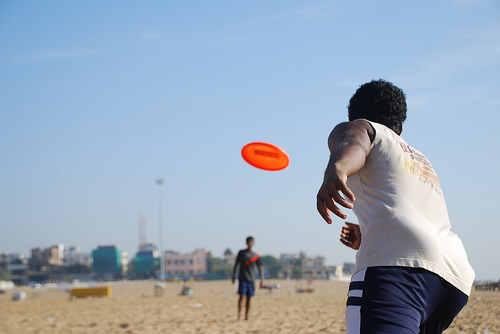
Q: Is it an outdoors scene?
A: Yes, it is outdoors.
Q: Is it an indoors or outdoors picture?
A: It is outdoors.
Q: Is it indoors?
A: No, it is outdoors.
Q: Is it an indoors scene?
A: No, it is outdoors.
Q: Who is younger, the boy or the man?
A: The boy is younger than the man.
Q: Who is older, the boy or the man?
A: The man is older than the boy.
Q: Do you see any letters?
A: Yes, there are letters.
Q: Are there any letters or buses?
A: Yes, there are letters.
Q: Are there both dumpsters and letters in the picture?
A: No, there are letters but no dumpsters.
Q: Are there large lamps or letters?
A: Yes, there are large letters.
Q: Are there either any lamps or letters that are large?
A: Yes, the letters are large.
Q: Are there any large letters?
A: Yes, there are large letters.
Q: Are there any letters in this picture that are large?
A: Yes, there are letters that are large.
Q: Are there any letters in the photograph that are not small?
A: Yes, there are large letters.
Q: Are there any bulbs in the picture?
A: No, there are no bulbs.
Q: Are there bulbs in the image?
A: No, there are no bulbs.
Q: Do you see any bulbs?
A: No, there are no bulbs.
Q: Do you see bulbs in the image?
A: No, there are no bulbs.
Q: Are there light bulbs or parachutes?
A: No, there are no light bulbs or parachutes.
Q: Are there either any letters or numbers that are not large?
A: No, there are letters but they are large.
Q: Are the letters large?
A: Yes, the letters are large.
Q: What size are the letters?
A: The letters are large.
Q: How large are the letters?
A: The letters are large.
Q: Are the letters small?
A: No, the letters are large.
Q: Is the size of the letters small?
A: No, the letters are large.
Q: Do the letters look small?
A: No, the letters are large.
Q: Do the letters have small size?
A: No, the letters are large.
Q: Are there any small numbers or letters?
A: No, there are letters but they are large.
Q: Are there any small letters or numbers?
A: No, there are letters but they are large.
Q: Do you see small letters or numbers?
A: No, there are letters but they are large.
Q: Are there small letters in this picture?
A: No, there are letters but they are large.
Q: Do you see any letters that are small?
A: No, there are letters but they are large.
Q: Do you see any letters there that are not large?
A: No, there are letters but they are large.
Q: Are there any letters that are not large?
A: No, there are letters but they are large.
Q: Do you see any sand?
A: Yes, there is sand.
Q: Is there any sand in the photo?
A: Yes, there is sand.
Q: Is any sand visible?
A: Yes, there is sand.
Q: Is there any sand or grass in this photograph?
A: Yes, there is sand.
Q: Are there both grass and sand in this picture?
A: No, there is sand but no grass.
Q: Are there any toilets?
A: No, there are no toilets.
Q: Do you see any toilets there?
A: No, there are no toilets.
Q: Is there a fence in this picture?
A: No, there are no fences.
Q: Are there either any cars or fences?
A: No, there are no fences or cars.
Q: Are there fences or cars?
A: No, there are no fences or cars.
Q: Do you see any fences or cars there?
A: No, there are no fences or cars.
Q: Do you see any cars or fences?
A: No, there are no fences or cars.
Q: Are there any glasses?
A: No, there are no glasses.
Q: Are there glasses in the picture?
A: No, there are no glasses.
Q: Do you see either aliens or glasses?
A: No, there are no glasses or aliens.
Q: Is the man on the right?
A: Yes, the man is on the right of the image.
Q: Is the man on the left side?
A: No, the man is on the right of the image.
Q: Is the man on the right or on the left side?
A: The man is on the right of the image.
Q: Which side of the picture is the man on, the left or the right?
A: The man is on the right of the image.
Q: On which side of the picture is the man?
A: The man is on the right of the image.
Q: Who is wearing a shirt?
A: The man is wearing a shirt.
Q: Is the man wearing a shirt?
A: Yes, the man is wearing a shirt.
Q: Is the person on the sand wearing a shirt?
A: Yes, the man is wearing a shirt.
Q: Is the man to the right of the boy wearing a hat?
A: No, the man is wearing a shirt.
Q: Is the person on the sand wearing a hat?
A: No, the man is wearing a shirt.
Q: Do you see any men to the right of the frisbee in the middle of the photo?
A: Yes, there is a man to the right of the frisbee.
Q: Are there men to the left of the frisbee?
A: No, the man is to the right of the frisbee.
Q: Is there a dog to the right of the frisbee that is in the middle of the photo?
A: No, there is a man to the right of the frisbee.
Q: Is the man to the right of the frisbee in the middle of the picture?
A: Yes, the man is to the right of the frisbee.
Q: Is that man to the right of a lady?
A: No, the man is to the right of the frisbee.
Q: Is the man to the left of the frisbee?
A: No, the man is to the right of the frisbee.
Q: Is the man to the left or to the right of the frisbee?
A: The man is to the right of the frisbee.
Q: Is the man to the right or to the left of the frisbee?
A: The man is to the right of the frisbee.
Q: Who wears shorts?
A: The man wears shorts.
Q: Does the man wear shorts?
A: Yes, the man wears shorts.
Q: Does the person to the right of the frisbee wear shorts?
A: Yes, the man wears shorts.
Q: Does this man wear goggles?
A: No, the man wears shorts.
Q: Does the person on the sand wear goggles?
A: No, the man wears shorts.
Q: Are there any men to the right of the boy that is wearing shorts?
A: Yes, there is a man to the right of the boy.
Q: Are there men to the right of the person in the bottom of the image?
A: Yes, there is a man to the right of the boy.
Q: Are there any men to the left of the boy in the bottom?
A: No, the man is to the right of the boy.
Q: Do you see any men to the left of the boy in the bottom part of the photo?
A: No, the man is to the right of the boy.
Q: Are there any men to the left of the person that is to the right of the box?
A: No, the man is to the right of the boy.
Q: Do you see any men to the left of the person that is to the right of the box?
A: No, the man is to the right of the boy.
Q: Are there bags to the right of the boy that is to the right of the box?
A: No, there is a man to the right of the boy.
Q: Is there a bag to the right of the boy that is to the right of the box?
A: No, there is a man to the right of the boy.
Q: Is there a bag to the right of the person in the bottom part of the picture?
A: No, there is a man to the right of the boy.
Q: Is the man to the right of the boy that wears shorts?
A: Yes, the man is to the right of the boy.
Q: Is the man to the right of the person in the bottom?
A: Yes, the man is to the right of the boy.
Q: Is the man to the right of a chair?
A: No, the man is to the right of the boy.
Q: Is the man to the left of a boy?
A: No, the man is to the right of a boy.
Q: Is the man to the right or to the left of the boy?
A: The man is to the right of the boy.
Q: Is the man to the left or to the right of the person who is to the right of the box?
A: The man is to the right of the boy.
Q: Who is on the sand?
A: The man is on the sand.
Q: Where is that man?
A: The man is on the sand.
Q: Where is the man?
A: The man is on the sand.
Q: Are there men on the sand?
A: Yes, there is a man on the sand.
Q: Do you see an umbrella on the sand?
A: No, there is a man on the sand.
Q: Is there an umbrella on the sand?
A: No, there is a man on the sand.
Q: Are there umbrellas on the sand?
A: No, there is a man on the sand.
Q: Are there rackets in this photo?
A: No, there are no rackets.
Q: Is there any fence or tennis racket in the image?
A: No, there are no rackets or fences.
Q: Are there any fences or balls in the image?
A: No, there are no fences or balls.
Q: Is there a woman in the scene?
A: No, there are no women.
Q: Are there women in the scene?
A: No, there are no women.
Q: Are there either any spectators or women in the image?
A: No, there are no women or spectators.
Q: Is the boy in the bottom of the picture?
A: Yes, the boy is in the bottom of the image.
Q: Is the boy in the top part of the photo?
A: No, the boy is in the bottom of the image.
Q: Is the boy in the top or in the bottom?
A: The boy is in the bottom of the image.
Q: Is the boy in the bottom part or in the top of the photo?
A: The boy is in the bottom of the image.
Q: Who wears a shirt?
A: The boy wears a shirt.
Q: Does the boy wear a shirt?
A: Yes, the boy wears a shirt.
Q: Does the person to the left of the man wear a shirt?
A: Yes, the boy wears a shirt.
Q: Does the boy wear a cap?
A: No, the boy wears a shirt.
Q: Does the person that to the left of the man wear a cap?
A: No, the boy wears a shirt.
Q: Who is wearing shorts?
A: The boy is wearing shorts.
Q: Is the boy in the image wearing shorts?
A: Yes, the boy is wearing shorts.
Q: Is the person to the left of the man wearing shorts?
A: Yes, the boy is wearing shorts.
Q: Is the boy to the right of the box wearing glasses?
A: No, the boy is wearing shorts.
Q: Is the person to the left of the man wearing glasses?
A: No, the boy is wearing shorts.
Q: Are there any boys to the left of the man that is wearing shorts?
A: Yes, there is a boy to the left of the man.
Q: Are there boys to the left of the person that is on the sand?
A: Yes, there is a boy to the left of the man.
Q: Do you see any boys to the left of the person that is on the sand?
A: Yes, there is a boy to the left of the man.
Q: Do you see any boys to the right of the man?
A: No, the boy is to the left of the man.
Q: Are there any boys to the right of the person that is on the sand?
A: No, the boy is to the left of the man.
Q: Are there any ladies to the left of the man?
A: No, there is a boy to the left of the man.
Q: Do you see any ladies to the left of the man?
A: No, there is a boy to the left of the man.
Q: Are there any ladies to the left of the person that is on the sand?
A: No, there is a boy to the left of the man.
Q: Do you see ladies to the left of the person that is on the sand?
A: No, there is a boy to the left of the man.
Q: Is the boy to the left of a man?
A: Yes, the boy is to the left of a man.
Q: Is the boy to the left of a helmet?
A: No, the boy is to the left of a man.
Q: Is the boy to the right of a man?
A: No, the boy is to the left of a man.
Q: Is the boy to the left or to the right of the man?
A: The boy is to the left of the man.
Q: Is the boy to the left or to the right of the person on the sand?
A: The boy is to the left of the man.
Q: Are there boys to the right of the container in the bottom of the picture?
A: Yes, there is a boy to the right of the box.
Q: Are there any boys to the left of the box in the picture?
A: No, the boy is to the right of the box.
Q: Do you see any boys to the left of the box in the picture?
A: No, the boy is to the right of the box.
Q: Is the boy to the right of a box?
A: Yes, the boy is to the right of a box.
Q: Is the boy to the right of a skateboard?
A: No, the boy is to the right of a box.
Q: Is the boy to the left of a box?
A: No, the boy is to the right of a box.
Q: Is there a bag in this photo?
A: No, there are no bags.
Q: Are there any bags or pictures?
A: No, there are no bags or pictures.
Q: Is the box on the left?
A: Yes, the box is on the left of the image.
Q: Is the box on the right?
A: No, the box is on the left of the image.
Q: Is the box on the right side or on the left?
A: The box is on the left of the image.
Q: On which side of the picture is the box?
A: The box is on the left of the image.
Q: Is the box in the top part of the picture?
A: No, the box is in the bottom of the image.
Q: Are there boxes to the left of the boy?
A: Yes, there is a box to the left of the boy.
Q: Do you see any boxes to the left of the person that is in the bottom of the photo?
A: Yes, there is a box to the left of the boy.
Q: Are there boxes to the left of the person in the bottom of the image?
A: Yes, there is a box to the left of the boy.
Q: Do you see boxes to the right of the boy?
A: No, the box is to the left of the boy.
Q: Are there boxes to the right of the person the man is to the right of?
A: No, the box is to the left of the boy.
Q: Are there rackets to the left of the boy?
A: No, there is a box to the left of the boy.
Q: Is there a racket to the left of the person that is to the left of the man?
A: No, there is a box to the left of the boy.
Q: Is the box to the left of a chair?
A: No, the box is to the left of the boy.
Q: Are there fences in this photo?
A: No, there are no fences.